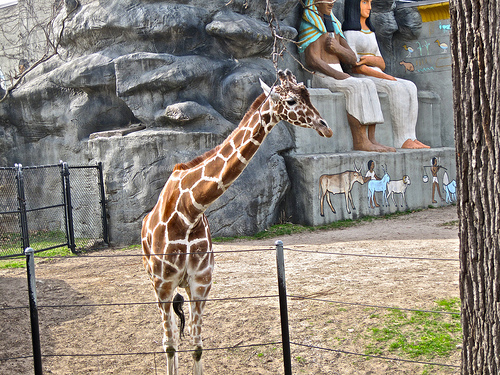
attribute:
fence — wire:
[14, 238, 462, 368]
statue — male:
[300, 0, 397, 152]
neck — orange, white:
[189, 109, 273, 216]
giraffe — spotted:
[136, 67, 341, 373]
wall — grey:
[0, 1, 303, 248]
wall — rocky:
[11, 0, 277, 220]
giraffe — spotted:
[160, 86, 367, 358]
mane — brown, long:
[214, 100, 267, 139]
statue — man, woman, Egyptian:
[311, 2, 435, 149]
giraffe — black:
[80, 37, 309, 307]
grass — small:
[338, 255, 450, 373]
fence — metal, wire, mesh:
[0, 161, 462, 373]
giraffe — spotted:
[78, 51, 368, 338]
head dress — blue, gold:
[293, 0, 348, 52]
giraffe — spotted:
[154, 74, 321, 260]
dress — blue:
[294, 4, 344, 54]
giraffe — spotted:
[99, 62, 317, 372]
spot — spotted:
[183, 177, 232, 218]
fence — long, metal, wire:
[0, 238, 499, 373]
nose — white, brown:
[309, 110, 339, 145]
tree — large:
[443, 0, 490, 369]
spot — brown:
[216, 155, 246, 180]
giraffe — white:
[114, 61, 336, 361]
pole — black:
[228, 226, 327, 361]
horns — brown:
[271, 63, 293, 85]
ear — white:
[251, 78, 275, 101]